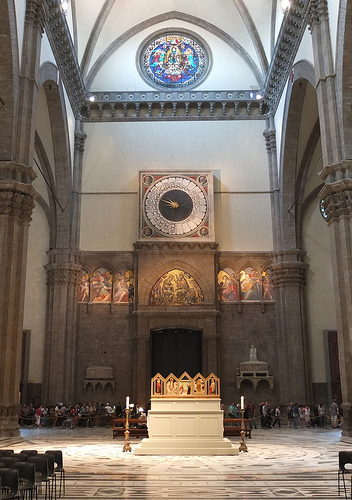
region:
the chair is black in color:
[12, 461, 39, 498]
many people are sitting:
[22, 399, 118, 424]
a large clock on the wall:
[136, 169, 216, 243]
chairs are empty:
[0, 446, 65, 496]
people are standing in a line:
[228, 397, 343, 427]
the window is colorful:
[133, 28, 212, 86]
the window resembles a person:
[138, 25, 209, 89]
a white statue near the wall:
[248, 345, 257, 361]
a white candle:
[122, 395, 132, 410]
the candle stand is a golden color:
[121, 408, 131, 453]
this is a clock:
[138, 159, 218, 241]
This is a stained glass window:
[113, 20, 229, 85]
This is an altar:
[127, 368, 272, 474]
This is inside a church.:
[24, 253, 312, 475]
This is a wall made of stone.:
[68, 318, 143, 369]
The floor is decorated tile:
[92, 460, 307, 498]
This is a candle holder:
[233, 398, 258, 451]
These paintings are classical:
[66, 251, 281, 315]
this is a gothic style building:
[37, 166, 320, 431]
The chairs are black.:
[3, 452, 68, 494]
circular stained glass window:
[137, 25, 215, 86]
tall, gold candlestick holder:
[121, 409, 134, 455]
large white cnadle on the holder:
[237, 394, 248, 410]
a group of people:
[226, 392, 340, 431]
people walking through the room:
[224, 397, 338, 429]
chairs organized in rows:
[2, 446, 65, 498]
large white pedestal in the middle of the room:
[133, 398, 236, 455]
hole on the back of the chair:
[344, 460, 351, 470]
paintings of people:
[220, 269, 277, 301]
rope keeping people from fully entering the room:
[18, 409, 340, 425]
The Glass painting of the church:
[138, 25, 210, 93]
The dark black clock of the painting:
[131, 160, 220, 253]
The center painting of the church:
[149, 272, 198, 307]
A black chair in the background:
[330, 447, 351, 499]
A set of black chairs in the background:
[0, 446, 69, 499]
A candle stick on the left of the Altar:
[111, 394, 136, 460]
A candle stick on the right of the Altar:
[226, 389, 260, 455]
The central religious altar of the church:
[136, 360, 236, 475]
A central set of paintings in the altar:
[143, 366, 226, 400]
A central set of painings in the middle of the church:
[80, 265, 279, 306]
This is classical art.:
[124, 1, 215, 90]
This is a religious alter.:
[139, 363, 229, 412]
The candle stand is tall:
[109, 381, 138, 450]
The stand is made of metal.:
[115, 413, 136, 447]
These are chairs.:
[5, 440, 62, 488]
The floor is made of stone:
[80, 456, 288, 495]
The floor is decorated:
[85, 453, 314, 497]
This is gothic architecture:
[33, 222, 328, 415]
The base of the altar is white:
[144, 405, 221, 461]